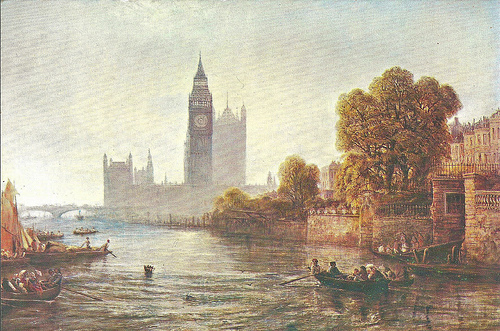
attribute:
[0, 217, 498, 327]
water — choppy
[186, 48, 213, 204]
clock tower — tall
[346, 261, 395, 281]
people — riding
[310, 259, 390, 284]
people — rowing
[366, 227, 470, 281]
boat — unloading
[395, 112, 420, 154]
leaves — large, light green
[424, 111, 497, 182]
buildings — overlooking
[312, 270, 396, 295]
rowboat — dark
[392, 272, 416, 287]
rowboat — dark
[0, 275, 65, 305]
rowboat — dark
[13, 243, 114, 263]
rowboat — dark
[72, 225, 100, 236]
rowboat — dark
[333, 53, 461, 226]
tree — orange, green, tall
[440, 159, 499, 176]
fencing — metal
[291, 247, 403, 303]
people — riding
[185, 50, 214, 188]
clock tower — tall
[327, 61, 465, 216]
trees — growing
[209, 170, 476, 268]
walls — large, stone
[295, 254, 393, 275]
men — rowing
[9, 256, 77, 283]
people — rowing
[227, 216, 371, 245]
walls — brick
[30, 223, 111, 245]
boat — passing under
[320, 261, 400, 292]
people — riding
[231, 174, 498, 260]
wall — brick